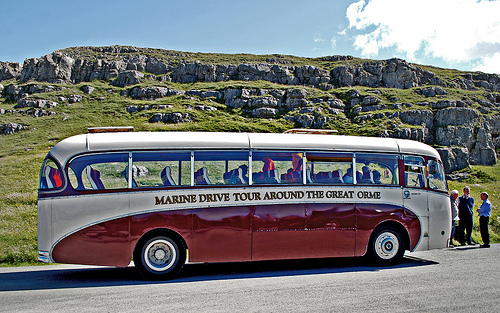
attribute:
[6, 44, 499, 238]
hills — rocky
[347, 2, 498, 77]
clouds — white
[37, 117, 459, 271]
bus — black, white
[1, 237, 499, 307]
road — gray, paved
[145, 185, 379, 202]
text — red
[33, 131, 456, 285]
bus — red, silver,  red and white,  marine's, old fashioned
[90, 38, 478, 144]
landscape — rocky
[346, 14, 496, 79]
cloud — fluffy, white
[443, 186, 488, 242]
man — standing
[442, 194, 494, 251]
men — standing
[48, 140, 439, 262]
bus — red, white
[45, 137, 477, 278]
bus — shiny, labeled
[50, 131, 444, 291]
bus — red, parked, white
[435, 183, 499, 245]
people — standing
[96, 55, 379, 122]
landscape — rocky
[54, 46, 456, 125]
landscape — rocky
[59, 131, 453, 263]
bus — red, white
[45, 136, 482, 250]
bus — red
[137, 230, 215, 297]
wheel — small, black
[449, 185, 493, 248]
people — three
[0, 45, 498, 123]
mountain —  small